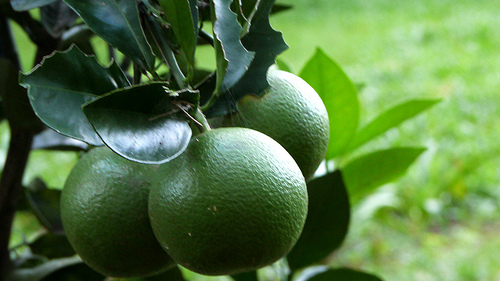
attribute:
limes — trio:
[29, 40, 358, 278]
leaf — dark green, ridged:
[19, 46, 114, 148]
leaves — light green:
[283, 41, 438, 208]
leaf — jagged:
[63, 0, 158, 72]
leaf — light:
[78, 47, 192, 121]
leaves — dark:
[70, 32, 185, 128]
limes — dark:
[105, 111, 305, 257]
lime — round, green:
[141, 121, 312, 278]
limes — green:
[96, 105, 280, 224]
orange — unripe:
[57, 143, 181, 275]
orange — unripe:
[152, 114, 312, 259]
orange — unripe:
[223, 49, 323, 174]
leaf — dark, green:
[266, 50, 416, 198]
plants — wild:
[269, 0, 498, 280]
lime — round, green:
[142, 111, 319, 277]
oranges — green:
[98, 114, 311, 264]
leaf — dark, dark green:
[80, 81, 200, 164]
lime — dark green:
[147, 130, 330, 274]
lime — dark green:
[35, 129, 206, 279]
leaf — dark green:
[54, 56, 229, 156]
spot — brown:
[204, 182, 223, 222]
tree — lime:
[0, 7, 466, 278]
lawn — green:
[363, 104, 496, 270]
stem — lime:
[165, 52, 204, 132]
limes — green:
[59, 65, 329, 273]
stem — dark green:
[140, 19, 210, 129]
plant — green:
[3, 2, 446, 279]